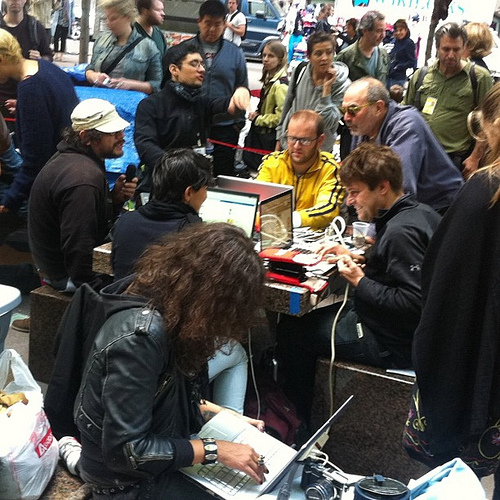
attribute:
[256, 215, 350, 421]
cord — WHITE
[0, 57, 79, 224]
sweater — blue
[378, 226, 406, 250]
jacket — BLACK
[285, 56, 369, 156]
hoodie — GRAY